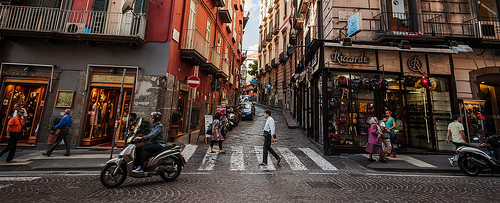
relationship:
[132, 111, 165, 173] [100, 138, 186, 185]
man riding motorcycle